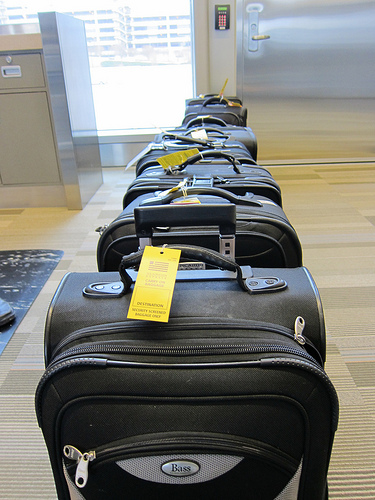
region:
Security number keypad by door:
[215, 4, 230, 31]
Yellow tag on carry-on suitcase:
[125, 244, 181, 322]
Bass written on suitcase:
[159, 458, 200, 475]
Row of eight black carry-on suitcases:
[43, 93, 339, 499]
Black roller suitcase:
[34, 245, 340, 499]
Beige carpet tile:
[5, 209, 99, 233]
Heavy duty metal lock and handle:
[248, 8, 270, 50]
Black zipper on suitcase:
[43, 344, 326, 373]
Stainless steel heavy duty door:
[241, 1, 373, 164]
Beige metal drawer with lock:
[0, 53, 46, 87]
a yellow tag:
[128, 249, 183, 330]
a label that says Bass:
[158, 458, 205, 484]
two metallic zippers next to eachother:
[60, 444, 103, 490]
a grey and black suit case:
[70, 272, 311, 491]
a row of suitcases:
[90, 45, 349, 489]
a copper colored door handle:
[244, 6, 272, 64]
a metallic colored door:
[241, 9, 370, 124]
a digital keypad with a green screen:
[211, 3, 231, 34]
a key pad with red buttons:
[213, 6, 233, 33]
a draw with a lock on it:
[0, 49, 45, 77]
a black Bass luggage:
[33, 203, 338, 498]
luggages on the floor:
[32, 77, 340, 499]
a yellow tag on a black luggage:
[125, 243, 181, 322]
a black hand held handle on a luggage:
[117, 242, 245, 294]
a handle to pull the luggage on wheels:
[131, 202, 234, 263]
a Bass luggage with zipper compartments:
[34, 203, 339, 499]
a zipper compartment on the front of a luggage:
[61, 429, 304, 498]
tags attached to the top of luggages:
[125, 76, 242, 320]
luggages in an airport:
[0, 0, 371, 497]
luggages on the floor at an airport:
[0, 0, 371, 497]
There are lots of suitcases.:
[49, 83, 338, 491]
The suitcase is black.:
[40, 268, 332, 498]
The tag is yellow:
[129, 240, 179, 323]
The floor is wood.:
[314, 167, 374, 312]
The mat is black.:
[0, 246, 68, 353]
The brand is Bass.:
[158, 458, 204, 479]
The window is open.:
[60, 58, 196, 128]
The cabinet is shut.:
[0, 60, 111, 203]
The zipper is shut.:
[58, 443, 294, 484]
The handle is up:
[135, 211, 242, 264]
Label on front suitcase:
[161, 464, 203, 489]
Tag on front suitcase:
[140, 244, 187, 317]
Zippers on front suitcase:
[66, 443, 92, 490]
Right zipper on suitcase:
[292, 311, 309, 351]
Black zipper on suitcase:
[62, 333, 245, 380]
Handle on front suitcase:
[121, 238, 244, 285]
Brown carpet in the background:
[341, 368, 374, 464]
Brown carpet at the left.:
[25, 323, 45, 447]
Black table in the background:
[13, 251, 47, 297]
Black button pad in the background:
[216, 7, 239, 42]